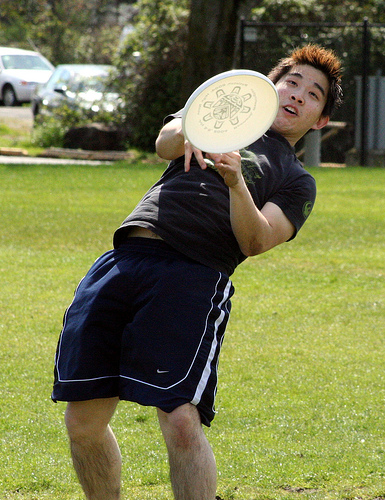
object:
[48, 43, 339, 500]
guy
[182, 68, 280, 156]
frisbee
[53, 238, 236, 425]
shorts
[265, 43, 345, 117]
hair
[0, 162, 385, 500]
grass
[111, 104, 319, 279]
tshirt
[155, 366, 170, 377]
logo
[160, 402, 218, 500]
leg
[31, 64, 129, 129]
car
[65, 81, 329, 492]
man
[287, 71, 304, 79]
eyebrow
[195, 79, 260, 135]
design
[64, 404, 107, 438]
knee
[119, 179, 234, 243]
stomach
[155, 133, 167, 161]
elbow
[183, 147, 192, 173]
finger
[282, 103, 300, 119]
mouth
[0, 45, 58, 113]
vehicle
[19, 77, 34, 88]
light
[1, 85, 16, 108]
tire